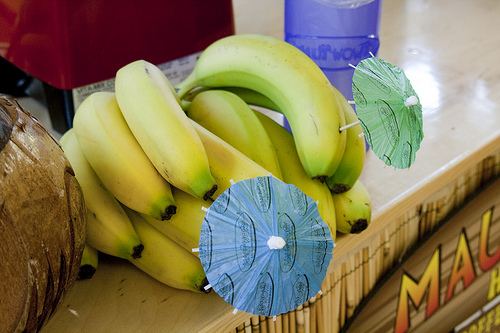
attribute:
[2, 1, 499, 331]
countertop — white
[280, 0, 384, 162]
bottle — blue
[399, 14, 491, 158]
table — tan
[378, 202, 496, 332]
lettering — orange and yellow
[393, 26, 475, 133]
table — made of wood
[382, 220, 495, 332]
lettering — yellow and orange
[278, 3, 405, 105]
cup — blue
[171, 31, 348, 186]
bananas — bunch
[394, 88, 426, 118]
tip — white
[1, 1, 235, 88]
cloth — red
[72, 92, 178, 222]
banana — bunch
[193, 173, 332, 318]
umbrella — mini, blue and black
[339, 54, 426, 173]
umbrella — green, small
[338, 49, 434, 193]
umbrella — green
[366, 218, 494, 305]
letters — colorful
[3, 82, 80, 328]
decoration — curved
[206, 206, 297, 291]
umbrella — small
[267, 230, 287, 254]
umbrella top — white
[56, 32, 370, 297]
bananas — bunch, yellow, green, greenish 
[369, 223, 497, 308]
letters — yellow, orange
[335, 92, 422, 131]
handle — white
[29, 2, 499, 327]
stand — wooden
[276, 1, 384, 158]
cup — blue